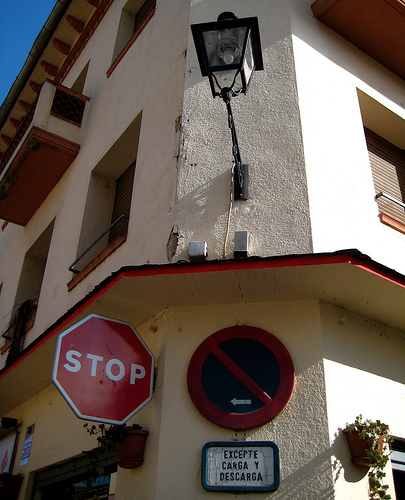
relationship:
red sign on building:
[52, 313, 156, 428] [0, 0, 405, 498]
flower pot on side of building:
[343, 414, 394, 467] [0, 0, 405, 498]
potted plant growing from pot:
[339, 411, 391, 498] [339, 426, 384, 466]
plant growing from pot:
[81, 421, 144, 453] [111, 425, 149, 469]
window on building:
[360, 91, 402, 251] [68, 30, 401, 259]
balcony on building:
[61, 166, 163, 288] [36, 21, 399, 486]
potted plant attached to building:
[339, 411, 391, 498] [0, 0, 405, 498]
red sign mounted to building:
[52, 313, 156, 428] [0, 0, 405, 498]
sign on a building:
[198, 434, 283, 498] [0, 0, 405, 498]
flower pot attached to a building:
[343, 425, 387, 469] [0, 0, 405, 498]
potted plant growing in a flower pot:
[339, 411, 391, 498] [343, 414, 394, 467]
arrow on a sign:
[226, 395, 256, 408] [197, 435, 290, 495]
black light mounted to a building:
[185, 5, 274, 212] [0, 0, 405, 498]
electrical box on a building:
[179, 237, 216, 263] [0, 0, 405, 498]